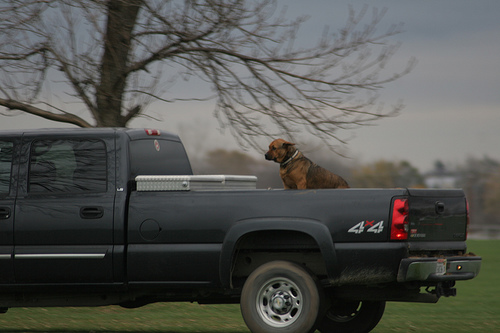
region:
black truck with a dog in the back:
[5, 115, 472, 317]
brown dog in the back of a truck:
[255, 123, 357, 197]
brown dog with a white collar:
[230, 126, 366, 205]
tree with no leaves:
[9, 4, 416, 121]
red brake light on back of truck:
[385, 192, 415, 253]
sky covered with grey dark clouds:
[39, 18, 479, 125]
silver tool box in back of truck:
[139, 161, 264, 193]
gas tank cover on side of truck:
[133, 213, 168, 253]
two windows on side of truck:
[2, 130, 116, 205]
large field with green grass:
[19, 244, 499, 329]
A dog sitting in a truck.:
[260, 138, 351, 189]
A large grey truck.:
[0, 129, 483, 329]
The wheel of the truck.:
[240, 259, 320, 331]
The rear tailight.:
[389, 193, 406, 243]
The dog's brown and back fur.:
[295, 164, 321, 180]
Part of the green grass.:
[426, 315, 480, 331]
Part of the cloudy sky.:
[434, 36, 488, 97]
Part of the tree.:
[74, 18, 161, 90]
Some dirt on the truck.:
[341, 268, 393, 282]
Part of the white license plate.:
[436, 259, 448, 275]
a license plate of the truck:
[433, 258, 448, 278]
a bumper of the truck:
[398, 253, 483, 285]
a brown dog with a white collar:
[260, 133, 351, 191]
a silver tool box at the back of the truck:
[131, 169, 261, 192]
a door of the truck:
[7, 126, 119, 304]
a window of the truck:
[22, 135, 111, 196]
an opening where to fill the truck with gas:
[133, 215, 165, 243]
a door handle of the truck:
[78, 205, 102, 220]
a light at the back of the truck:
[463, 196, 471, 238]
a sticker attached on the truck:
[151, 138, 162, 152]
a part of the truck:
[5, 119, 484, 331]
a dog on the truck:
[261, 132, 351, 195]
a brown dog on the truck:
[261, 133, 351, 191]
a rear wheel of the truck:
[236, 258, 329, 332]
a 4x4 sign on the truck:
[347, 216, 386, 239]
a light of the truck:
[386, 195, 413, 241]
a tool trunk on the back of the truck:
[133, 170, 260, 190]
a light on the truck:
[143, 125, 163, 139]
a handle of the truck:
[77, 205, 104, 220]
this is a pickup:
[21, 145, 391, 303]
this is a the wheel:
[242, 263, 317, 330]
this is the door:
[28, 148, 99, 181]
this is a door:
[251, 137, 317, 178]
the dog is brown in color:
[291, 161, 318, 182]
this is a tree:
[143, 11, 310, 92]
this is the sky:
[443, 20, 496, 119]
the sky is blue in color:
[433, 47, 470, 110]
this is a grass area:
[441, 301, 490, 326]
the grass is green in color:
[437, 308, 475, 329]